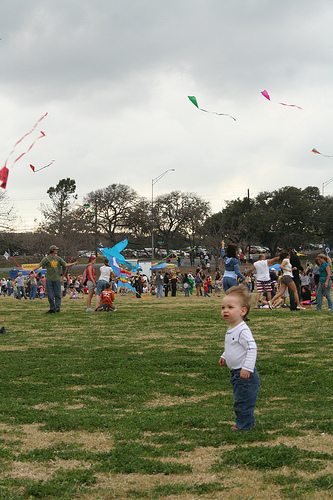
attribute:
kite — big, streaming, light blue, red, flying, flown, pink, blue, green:
[259, 88, 283, 107]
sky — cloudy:
[173, 40, 211, 67]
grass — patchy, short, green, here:
[138, 361, 187, 383]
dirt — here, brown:
[157, 396, 177, 404]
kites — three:
[185, 84, 286, 122]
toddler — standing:
[205, 280, 258, 416]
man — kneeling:
[77, 251, 105, 318]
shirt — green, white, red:
[97, 292, 111, 304]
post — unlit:
[144, 184, 160, 209]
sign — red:
[1, 175, 11, 183]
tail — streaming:
[8, 105, 48, 150]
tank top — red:
[83, 267, 91, 283]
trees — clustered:
[153, 216, 206, 243]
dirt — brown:
[20, 424, 319, 495]